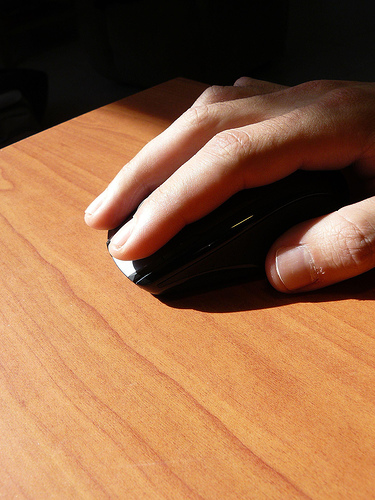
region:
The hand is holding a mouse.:
[80, 71, 373, 299]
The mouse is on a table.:
[104, 190, 291, 327]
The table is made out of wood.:
[46, 345, 205, 420]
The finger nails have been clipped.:
[268, 243, 315, 301]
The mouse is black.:
[133, 236, 233, 302]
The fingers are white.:
[86, 171, 204, 259]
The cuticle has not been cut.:
[304, 248, 329, 290]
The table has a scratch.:
[95, 436, 214, 477]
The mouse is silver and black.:
[103, 229, 201, 290]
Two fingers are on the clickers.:
[73, 126, 254, 294]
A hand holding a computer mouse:
[5, 18, 373, 496]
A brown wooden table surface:
[49, 311, 342, 474]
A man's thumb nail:
[267, 239, 328, 306]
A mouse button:
[108, 249, 228, 281]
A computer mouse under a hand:
[41, 62, 374, 310]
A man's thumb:
[242, 191, 373, 303]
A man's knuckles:
[298, 73, 373, 163]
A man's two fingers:
[68, 180, 188, 262]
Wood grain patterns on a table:
[43, 307, 194, 453]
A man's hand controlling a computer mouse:
[50, 28, 374, 334]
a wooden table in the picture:
[31, 330, 341, 493]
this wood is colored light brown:
[17, 343, 358, 487]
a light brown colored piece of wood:
[20, 354, 335, 484]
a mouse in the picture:
[87, 169, 327, 295]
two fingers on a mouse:
[75, 113, 253, 254]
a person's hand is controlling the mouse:
[57, 62, 362, 299]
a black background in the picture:
[29, 14, 247, 86]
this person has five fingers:
[82, 70, 352, 289]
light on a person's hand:
[24, 61, 333, 282]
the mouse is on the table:
[20, 84, 358, 347]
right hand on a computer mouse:
[86, 73, 372, 291]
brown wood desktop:
[1, 77, 362, 498]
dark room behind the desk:
[1, 1, 372, 143]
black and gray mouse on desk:
[109, 170, 352, 294]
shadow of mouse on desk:
[156, 284, 374, 309]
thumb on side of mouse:
[267, 194, 372, 294]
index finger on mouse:
[107, 118, 289, 261]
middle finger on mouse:
[82, 98, 268, 228]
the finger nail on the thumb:
[279, 248, 315, 289]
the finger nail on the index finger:
[108, 223, 132, 247]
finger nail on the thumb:
[270, 248, 315, 285]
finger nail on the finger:
[110, 219, 136, 247]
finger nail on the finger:
[86, 194, 105, 215]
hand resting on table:
[65, 67, 373, 310]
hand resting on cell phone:
[83, 45, 373, 297]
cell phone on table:
[106, 166, 320, 286]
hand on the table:
[85, 67, 374, 294]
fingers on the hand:
[78, 79, 373, 295]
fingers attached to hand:
[82, 71, 373, 290]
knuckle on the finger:
[189, 127, 258, 162]